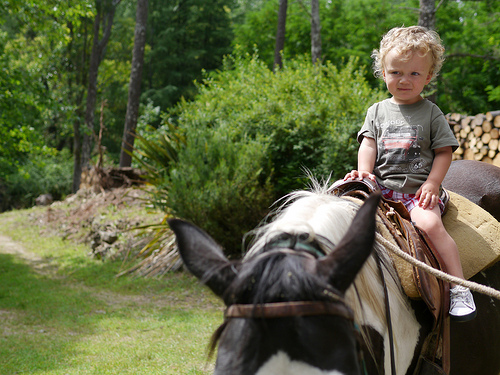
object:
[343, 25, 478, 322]
boy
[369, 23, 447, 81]
curly hair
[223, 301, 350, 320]
harness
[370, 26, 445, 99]
head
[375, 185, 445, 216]
shorts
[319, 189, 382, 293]
ear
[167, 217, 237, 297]
ear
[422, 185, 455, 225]
ground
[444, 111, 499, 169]
wood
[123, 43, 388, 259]
bush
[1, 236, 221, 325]
yes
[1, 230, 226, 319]
yes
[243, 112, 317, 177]
wall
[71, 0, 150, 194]
tree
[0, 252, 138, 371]
shadow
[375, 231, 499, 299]
beige rope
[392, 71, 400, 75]
child eyes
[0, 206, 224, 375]
grass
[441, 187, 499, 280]
blanket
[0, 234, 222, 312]
path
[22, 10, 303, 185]
woods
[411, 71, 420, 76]
eye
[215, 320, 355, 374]
face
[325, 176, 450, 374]
saddle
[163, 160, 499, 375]
horse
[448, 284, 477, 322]
shoe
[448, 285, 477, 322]
foot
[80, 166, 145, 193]
trunk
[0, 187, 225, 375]
ground